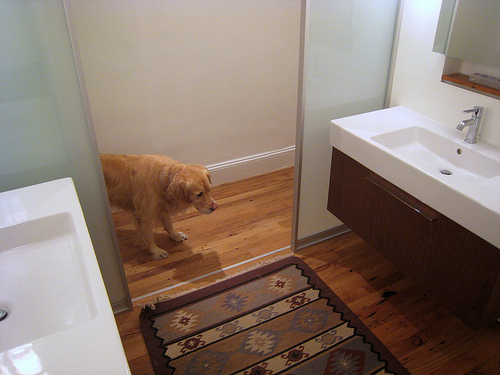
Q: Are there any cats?
A: No, there are no cats.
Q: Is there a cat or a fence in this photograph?
A: No, there are no cats or fences.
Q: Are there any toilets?
A: No, there are no toilets.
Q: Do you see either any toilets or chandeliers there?
A: No, there are no toilets or chandeliers.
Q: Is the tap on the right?
A: Yes, the tap is on the right of the image.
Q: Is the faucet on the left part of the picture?
A: No, the faucet is on the right of the image.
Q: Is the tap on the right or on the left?
A: The tap is on the right of the image.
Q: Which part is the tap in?
A: The tap is on the right of the image.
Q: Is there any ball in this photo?
A: No, there are no balls.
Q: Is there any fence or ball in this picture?
A: No, there are no balls or fences.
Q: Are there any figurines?
A: No, there are no figurines.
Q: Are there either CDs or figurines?
A: No, there are no figurines or cds.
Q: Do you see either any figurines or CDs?
A: No, there are no figurines or cds.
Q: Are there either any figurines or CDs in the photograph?
A: No, there are no figurines or cds.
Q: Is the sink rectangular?
A: Yes, the sink is rectangular.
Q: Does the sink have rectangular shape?
A: Yes, the sink is rectangular.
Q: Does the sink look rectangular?
A: Yes, the sink is rectangular.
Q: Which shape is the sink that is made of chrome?
A: The sink is rectangular.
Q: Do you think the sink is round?
A: No, the sink is rectangular.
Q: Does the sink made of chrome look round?
A: No, the sink is rectangular.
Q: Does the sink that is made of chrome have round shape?
A: No, the sink is rectangular.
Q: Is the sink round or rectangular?
A: The sink is rectangular.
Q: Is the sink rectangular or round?
A: The sink is rectangular.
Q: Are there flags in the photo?
A: No, there are no flags.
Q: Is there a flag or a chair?
A: No, there are no flags or chairs.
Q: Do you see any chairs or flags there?
A: No, there are no flags or chairs.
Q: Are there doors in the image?
A: Yes, there is a door.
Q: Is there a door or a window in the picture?
A: Yes, there is a door.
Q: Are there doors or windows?
A: Yes, there is a door.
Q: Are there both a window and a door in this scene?
A: No, there is a door but no windows.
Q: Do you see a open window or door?
A: Yes, there is an open door.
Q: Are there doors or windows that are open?
A: Yes, the door is open.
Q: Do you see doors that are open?
A: Yes, there is an open door.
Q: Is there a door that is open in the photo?
A: Yes, there is an open door.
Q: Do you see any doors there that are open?
A: Yes, there is a door that is open.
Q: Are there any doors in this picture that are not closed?
A: Yes, there is a open door.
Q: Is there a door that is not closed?
A: Yes, there is a open door.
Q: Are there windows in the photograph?
A: No, there are no windows.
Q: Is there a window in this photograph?
A: No, there are no windows.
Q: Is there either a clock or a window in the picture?
A: No, there are no windows or clocks.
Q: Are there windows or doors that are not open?
A: No, there is a door but it is open.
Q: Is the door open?
A: Yes, the door is open.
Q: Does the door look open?
A: Yes, the door is open.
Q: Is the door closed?
A: No, the door is open.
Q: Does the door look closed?
A: No, the door is open.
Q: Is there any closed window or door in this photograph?
A: No, there is a door but it is open.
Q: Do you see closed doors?
A: No, there is a door but it is open.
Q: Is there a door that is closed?
A: No, there is a door but it is open.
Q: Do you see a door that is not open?
A: No, there is a door but it is open.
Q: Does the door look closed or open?
A: The door is open.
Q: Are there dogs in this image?
A: Yes, there is a dog.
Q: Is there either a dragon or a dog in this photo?
A: Yes, there is a dog.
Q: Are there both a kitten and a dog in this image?
A: No, there is a dog but no kittens.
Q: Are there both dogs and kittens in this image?
A: No, there is a dog but no kittens.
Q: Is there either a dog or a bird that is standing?
A: Yes, the dog is standing.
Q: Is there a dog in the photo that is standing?
A: Yes, there is a dog that is standing.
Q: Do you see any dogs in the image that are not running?
A: Yes, there is a dog that is standing .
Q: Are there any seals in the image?
A: No, there are no seals.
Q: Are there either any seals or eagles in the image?
A: No, there are no seals or eagles.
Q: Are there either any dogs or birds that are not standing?
A: No, there is a dog but it is standing.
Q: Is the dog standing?
A: Yes, the dog is standing.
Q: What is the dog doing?
A: The dog is standing.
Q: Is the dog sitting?
A: No, the dog is standing.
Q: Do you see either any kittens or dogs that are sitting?
A: No, there is a dog but it is standing.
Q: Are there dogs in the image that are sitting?
A: No, there is a dog but it is standing.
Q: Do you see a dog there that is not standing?
A: No, there is a dog but it is standing.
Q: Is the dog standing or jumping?
A: The dog is standing.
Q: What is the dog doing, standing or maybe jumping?
A: The dog is standing.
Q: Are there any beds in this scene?
A: No, there are no beds.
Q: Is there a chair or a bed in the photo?
A: No, there are no beds or chairs.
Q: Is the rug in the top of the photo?
A: No, the rug is in the bottom of the image.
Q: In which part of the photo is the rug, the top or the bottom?
A: The rug is in the bottom of the image.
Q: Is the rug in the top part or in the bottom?
A: The rug is in the bottom of the image.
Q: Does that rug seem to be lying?
A: Yes, the rug is lying.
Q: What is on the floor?
A: The rug is on the floor.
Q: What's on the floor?
A: The rug is on the floor.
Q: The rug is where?
A: The rug is on the floor.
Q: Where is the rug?
A: The rug is on the floor.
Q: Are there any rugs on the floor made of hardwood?
A: Yes, there is a rug on the floor.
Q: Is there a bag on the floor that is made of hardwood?
A: No, there is a rug on the floor.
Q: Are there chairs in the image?
A: No, there are no chairs.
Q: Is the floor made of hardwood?
A: Yes, the floor is made of hardwood.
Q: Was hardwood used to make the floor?
A: Yes, the floor is made of hardwood.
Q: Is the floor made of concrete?
A: No, the floor is made of hardwood.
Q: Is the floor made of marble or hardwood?
A: The floor is made of hardwood.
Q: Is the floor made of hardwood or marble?
A: The floor is made of hardwood.